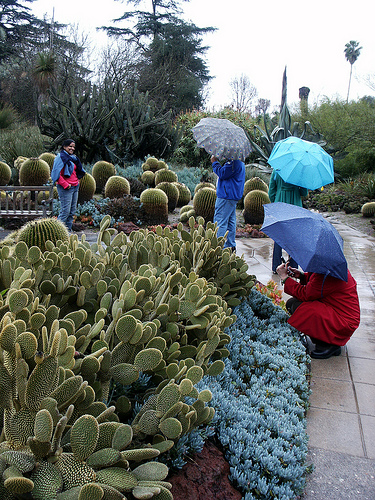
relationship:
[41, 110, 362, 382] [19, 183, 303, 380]
people in garden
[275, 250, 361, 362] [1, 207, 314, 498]
woman in garden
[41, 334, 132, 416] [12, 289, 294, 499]
cactus are in garden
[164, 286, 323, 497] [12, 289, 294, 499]
succulent in garden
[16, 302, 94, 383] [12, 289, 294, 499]
cacti in garden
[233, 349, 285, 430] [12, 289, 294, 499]
succulent in garden